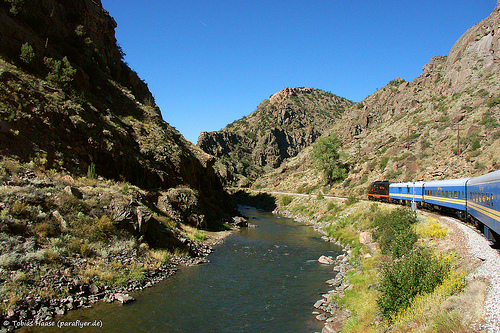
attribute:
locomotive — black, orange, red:
[361, 178, 389, 201]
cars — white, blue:
[389, 167, 500, 248]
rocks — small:
[318, 246, 352, 314]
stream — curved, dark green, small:
[49, 199, 334, 333]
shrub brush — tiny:
[372, 210, 447, 310]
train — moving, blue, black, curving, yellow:
[367, 170, 499, 246]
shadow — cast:
[230, 185, 283, 213]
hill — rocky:
[1, 1, 231, 216]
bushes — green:
[16, 43, 98, 111]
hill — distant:
[199, 69, 343, 163]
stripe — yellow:
[387, 191, 499, 218]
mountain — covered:
[203, 71, 402, 175]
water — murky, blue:
[238, 208, 310, 271]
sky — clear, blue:
[104, 1, 487, 154]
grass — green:
[337, 260, 382, 331]